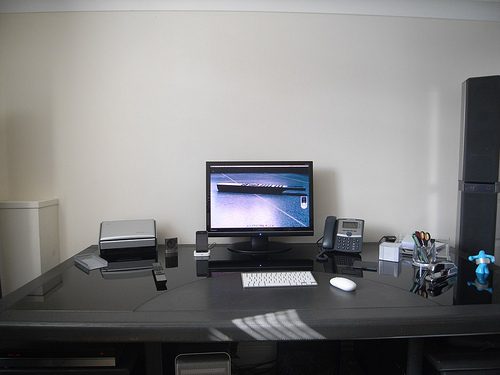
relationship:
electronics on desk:
[73, 160, 365, 292] [3, 240, 499, 341]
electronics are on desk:
[73, 160, 365, 292] [3, 240, 499, 341]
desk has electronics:
[3, 240, 499, 341] [73, 160, 365, 292]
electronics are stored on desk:
[73, 160, 365, 292] [3, 240, 499, 341]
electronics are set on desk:
[73, 160, 365, 292] [3, 240, 499, 341]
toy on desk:
[468, 247, 495, 276] [3, 240, 499, 341]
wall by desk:
[0, 14, 500, 261] [3, 240, 499, 341]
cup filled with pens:
[409, 242, 435, 265] [409, 231, 428, 262]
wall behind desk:
[0, 14, 500, 261] [3, 240, 499, 341]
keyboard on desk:
[238, 271, 317, 288] [3, 240, 499, 341]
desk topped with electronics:
[3, 240, 499, 341] [73, 160, 365, 292]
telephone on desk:
[315, 215, 365, 261] [3, 240, 499, 341]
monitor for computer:
[205, 159, 314, 253] [172, 343, 230, 374]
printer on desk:
[97, 218, 157, 258] [3, 240, 499, 341]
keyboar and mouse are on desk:
[238, 271, 357, 293] [3, 240, 499, 341]